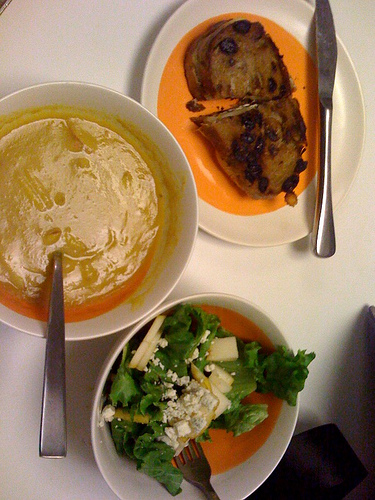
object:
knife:
[312, 1, 337, 258]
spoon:
[38, 250, 69, 459]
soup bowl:
[1, 80, 202, 341]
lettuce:
[104, 303, 317, 497]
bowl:
[90, 292, 301, 500]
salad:
[101, 302, 316, 497]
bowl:
[267, 392, 296, 426]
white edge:
[141, 3, 365, 248]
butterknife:
[313, 0, 338, 257]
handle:
[312, 99, 336, 258]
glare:
[311, 97, 335, 258]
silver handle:
[38, 255, 68, 459]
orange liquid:
[69, 289, 108, 309]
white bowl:
[91, 289, 313, 498]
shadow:
[27, 279, 187, 475]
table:
[0, 1, 375, 500]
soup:
[0, 103, 187, 323]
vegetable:
[100, 302, 315, 497]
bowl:
[0, 82, 198, 341]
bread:
[183, 18, 308, 208]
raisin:
[219, 36, 238, 56]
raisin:
[233, 19, 251, 34]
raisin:
[240, 132, 255, 144]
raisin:
[282, 174, 299, 192]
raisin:
[258, 176, 269, 193]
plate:
[139, 0, 365, 248]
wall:
[193, 98, 220, 113]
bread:
[184, 17, 298, 103]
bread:
[189, 94, 308, 208]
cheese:
[161, 365, 218, 448]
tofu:
[128, 312, 167, 372]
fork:
[173, 438, 219, 500]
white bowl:
[216, 476, 245, 497]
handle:
[38, 253, 66, 458]